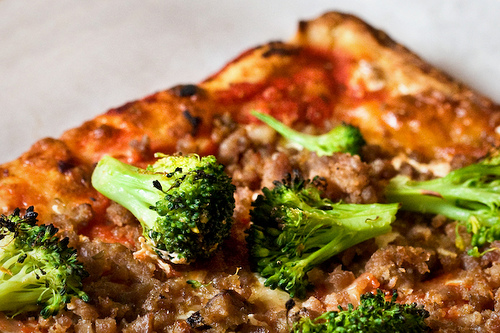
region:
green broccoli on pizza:
[98, 113, 245, 223]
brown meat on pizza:
[97, 222, 279, 330]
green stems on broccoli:
[70, 146, 177, 228]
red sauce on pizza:
[198, 67, 340, 132]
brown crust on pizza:
[287, 7, 464, 126]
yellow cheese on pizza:
[322, 52, 431, 181]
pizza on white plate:
[0, 60, 490, 220]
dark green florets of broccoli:
[151, 133, 256, 273]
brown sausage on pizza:
[133, 98, 383, 270]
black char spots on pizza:
[132, 67, 266, 138]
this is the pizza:
[12, 52, 478, 328]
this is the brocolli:
[117, 168, 224, 242]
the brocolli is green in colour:
[151, 158, 216, 255]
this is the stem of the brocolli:
[340, 199, 391, 240]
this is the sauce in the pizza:
[258, 55, 350, 112]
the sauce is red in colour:
[272, 56, 336, 114]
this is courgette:
[203, 289, 249, 329]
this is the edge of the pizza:
[295, 11, 404, 48]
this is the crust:
[371, 29, 427, 64]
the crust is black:
[375, 30, 399, 52]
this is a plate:
[50, 50, 100, 82]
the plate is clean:
[27, 41, 87, 95]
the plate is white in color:
[18, 17, 104, 92]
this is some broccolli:
[75, 142, 433, 295]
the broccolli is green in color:
[147, 174, 199, 221]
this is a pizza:
[260, 39, 424, 139]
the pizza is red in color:
[285, 49, 335, 124]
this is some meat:
[139, 287, 203, 329]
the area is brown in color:
[34, 159, 65, 186]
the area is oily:
[399, 118, 446, 135]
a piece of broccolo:
[83, 153, 250, 265]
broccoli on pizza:
[4, 3, 494, 330]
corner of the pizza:
[288, 2, 382, 52]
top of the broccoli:
[153, 173, 248, 273]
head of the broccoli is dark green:
[289, 295, 436, 331]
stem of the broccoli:
[89, 153, 160, 225]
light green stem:
[300, 188, 404, 261]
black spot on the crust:
[167, 80, 199, 101]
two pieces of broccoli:
[74, 143, 404, 296]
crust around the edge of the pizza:
[4, 3, 496, 161]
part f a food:
[413, 258, 445, 309]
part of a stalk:
[356, 190, 404, 250]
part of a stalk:
[273, 248, 298, 286]